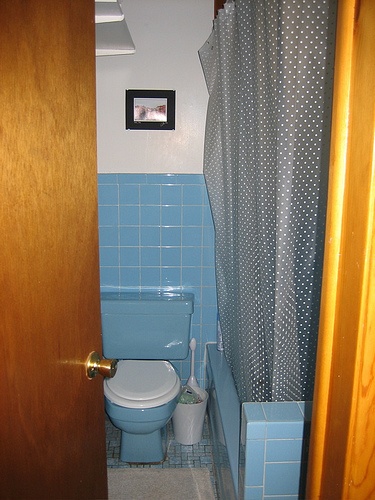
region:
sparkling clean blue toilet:
[99, 288, 189, 466]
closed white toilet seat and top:
[100, 357, 182, 405]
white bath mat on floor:
[110, 464, 217, 494]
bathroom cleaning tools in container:
[173, 336, 207, 444]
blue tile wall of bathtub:
[239, 399, 310, 498]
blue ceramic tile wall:
[100, 171, 214, 285]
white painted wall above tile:
[100, 1, 206, 174]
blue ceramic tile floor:
[169, 440, 216, 471]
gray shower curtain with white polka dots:
[194, 2, 325, 401]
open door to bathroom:
[1, 1, 105, 499]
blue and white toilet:
[98, 287, 203, 472]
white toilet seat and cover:
[102, 355, 183, 419]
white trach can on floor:
[169, 382, 209, 451]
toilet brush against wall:
[181, 329, 204, 390]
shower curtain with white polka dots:
[247, 238, 311, 361]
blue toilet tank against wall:
[102, 276, 197, 364]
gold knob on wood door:
[77, 341, 121, 387]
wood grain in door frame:
[354, 375, 370, 483]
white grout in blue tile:
[250, 431, 285, 489]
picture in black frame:
[115, 77, 188, 134]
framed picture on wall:
[122, 86, 177, 131]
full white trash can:
[173, 384, 207, 446]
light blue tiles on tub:
[238, 401, 303, 499]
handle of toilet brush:
[186, 335, 198, 384]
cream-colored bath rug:
[106, 463, 215, 498]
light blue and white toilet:
[98, 290, 195, 466]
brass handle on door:
[82, 350, 117, 380]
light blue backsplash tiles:
[97, 169, 214, 298]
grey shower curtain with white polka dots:
[202, 79, 311, 401]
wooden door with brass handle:
[1, 0, 111, 498]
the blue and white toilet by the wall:
[95, 289, 194, 463]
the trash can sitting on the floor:
[173, 382, 207, 450]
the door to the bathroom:
[1, 0, 106, 495]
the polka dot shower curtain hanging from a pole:
[194, 2, 334, 412]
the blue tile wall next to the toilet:
[97, 171, 218, 341]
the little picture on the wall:
[125, 85, 181, 132]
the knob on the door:
[87, 348, 117, 380]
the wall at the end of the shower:
[237, 401, 305, 498]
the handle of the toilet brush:
[188, 339, 199, 386]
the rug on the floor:
[113, 468, 214, 498]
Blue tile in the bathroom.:
[64, 162, 314, 497]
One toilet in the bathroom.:
[84, 252, 206, 471]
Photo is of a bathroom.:
[25, 7, 356, 488]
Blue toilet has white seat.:
[99, 358, 184, 412]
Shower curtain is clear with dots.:
[174, 10, 322, 410]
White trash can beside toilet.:
[167, 373, 211, 454]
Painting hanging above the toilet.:
[114, 80, 186, 135]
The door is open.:
[0, 0, 133, 498]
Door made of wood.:
[6, 2, 117, 495]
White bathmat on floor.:
[106, 463, 222, 498]